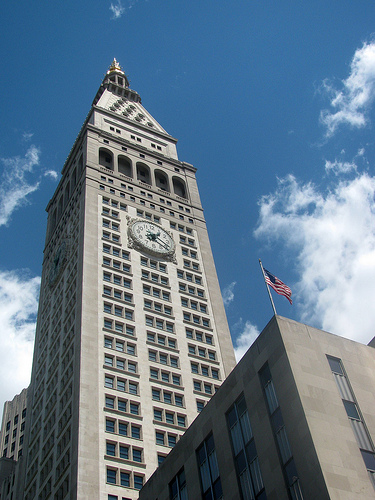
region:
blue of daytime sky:
[2, 1, 371, 495]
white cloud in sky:
[257, 162, 373, 336]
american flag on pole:
[257, 256, 292, 314]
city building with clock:
[19, 58, 237, 497]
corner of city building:
[136, 315, 373, 496]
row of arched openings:
[94, 145, 189, 198]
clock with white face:
[129, 218, 175, 254]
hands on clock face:
[150, 229, 170, 246]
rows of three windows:
[101, 263, 222, 416]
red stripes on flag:
[265, 276, 291, 302]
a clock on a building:
[124, 214, 180, 258]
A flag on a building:
[254, 253, 302, 326]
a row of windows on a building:
[108, 277, 143, 485]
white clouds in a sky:
[237, 47, 374, 254]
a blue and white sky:
[169, 1, 374, 129]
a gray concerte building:
[29, 55, 227, 379]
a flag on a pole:
[254, 261, 296, 320]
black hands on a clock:
[140, 224, 176, 248]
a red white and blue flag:
[251, 252, 293, 316]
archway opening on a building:
[91, 146, 197, 200]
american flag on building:
[251, 250, 297, 323]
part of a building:
[246, 363, 324, 478]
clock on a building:
[118, 198, 188, 275]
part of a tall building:
[27, 120, 260, 476]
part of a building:
[205, 365, 330, 473]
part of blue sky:
[225, 71, 308, 142]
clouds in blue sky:
[246, 197, 363, 292]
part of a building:
[51, 289, 188, 372]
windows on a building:
[103, 389, 143, 422]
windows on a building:
[141, 266, 173, 290]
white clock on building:
[127, 214, 180, 261]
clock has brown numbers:
[131, 222, 167, 240]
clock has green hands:
[130, 222, 166, 251]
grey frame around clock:
[132, 213, 174, 259]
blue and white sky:
[202, 101, 345, 251]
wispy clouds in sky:
[250, 146, 337, 281]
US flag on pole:
[251, 251, 285, 312]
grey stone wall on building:
[285, 326, 348, 491]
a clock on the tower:
[129, 217, 176, 262]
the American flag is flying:
[257, 257, 296, 319]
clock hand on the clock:
[147, 230, 170, 248]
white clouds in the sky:
[266, 179, 373, 309]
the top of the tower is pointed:
[105, 56, 125, 73]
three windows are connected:
[102, 438, 147, 464]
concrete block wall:
[267, 321, 368, 498]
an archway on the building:
[99, 144, 114, 172]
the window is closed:
[254, 364, 279, 417]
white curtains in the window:
[271, 428, 297, 463]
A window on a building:
[104, 316, 110, 327]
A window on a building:
[115, 320, 119, 328]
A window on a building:
[124, 325, 134, 333]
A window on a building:
[104, 337, 109, 346]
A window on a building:
[114, 341, 122, 351]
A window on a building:
[126, 343, 135, 355]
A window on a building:
[103, 356, 114, 365]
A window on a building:
[116, 358, 123, 368]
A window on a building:
[128, 363, 136, 371]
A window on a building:
[105, 221, 110, 225]